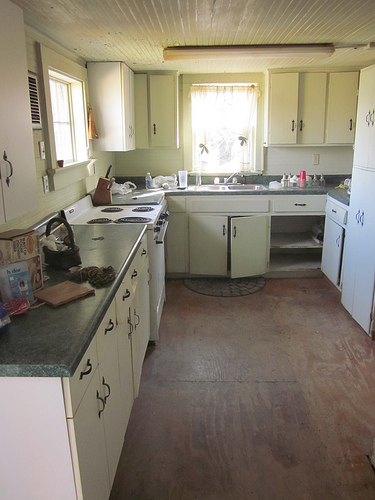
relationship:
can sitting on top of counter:
[296, 166, 307, 190] [200, 188, 346, 198]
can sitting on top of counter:
[296, 166, 307, 190] [108, 176, 351, 205]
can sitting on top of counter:
[1, 295, 29, 317] [0, 223, 147, 375]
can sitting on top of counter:
[296, 166, 307, 190] [87, 166, 353, 208]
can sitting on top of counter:
[298, 169, 307, 185] [102, 167, 352, 203]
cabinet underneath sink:
[188, 213, 272, 277] [203, 177, 275, 208]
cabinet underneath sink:
[270, 205, 320, 274] [206, 181, 264, 195]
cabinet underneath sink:
[188, 213, 272, 277] [190, 172, 267, 192]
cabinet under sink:
[161, 212, 343, 279] [187, 183, 268, 193]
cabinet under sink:
[188, 213, 272, 277] [196, 166, 264, 206]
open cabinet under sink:
[224, 210, 280, 275] [226, 181, 269, 192]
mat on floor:
[183, 276, 267, 296] [111, 278, 374, 498]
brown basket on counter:
[45, 216, 87, 259] [0, 223, 147, 375]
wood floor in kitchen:
[201, 354, 297, 447] [35, 171, 352, 417]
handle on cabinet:
[100, 376, 109, 403] [68, 346, 126, 498]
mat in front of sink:
[180, 276, 270, 299] [185, 182, 267, 193]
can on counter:
[296, 166, 307, 190] [126, 146, 345, 283]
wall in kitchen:
[98, 137, 183, 178] [5, 6, 372, 493]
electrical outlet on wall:
[40, 172, 51, 192] [35, 97, 373, 313]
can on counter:
[296, 166, 307, 190] [4, 209, 150, 345]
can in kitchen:
[296, 166, 307, 190] [2, 2, 373, 341]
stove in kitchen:
[65, 192, 164, 327] [5, 6, 372, 493]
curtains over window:
[190, 81, 260, 176] [188, 0, 261, 93]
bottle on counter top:
[133, 171, 189, 204] [102, 174, 348, 203]